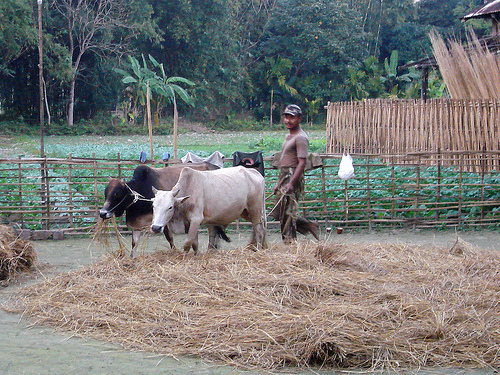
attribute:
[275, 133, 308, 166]
shirt — tan, brown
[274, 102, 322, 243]
man — walking, bare foot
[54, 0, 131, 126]
tree — green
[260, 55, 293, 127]
tree — green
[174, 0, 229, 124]
tree — green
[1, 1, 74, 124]
tree — green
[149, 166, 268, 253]
cow — walking, eating, cream, white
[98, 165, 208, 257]
cow — walking, eating, black, brown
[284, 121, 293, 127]
mustache — dark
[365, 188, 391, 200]
plant — green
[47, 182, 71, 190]
plant — green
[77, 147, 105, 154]
plant — green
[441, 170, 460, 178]
plant — green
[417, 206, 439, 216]
plant — green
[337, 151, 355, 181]
bag — white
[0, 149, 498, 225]
fence — tall, wooden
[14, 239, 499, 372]
pile of hay — brown, dry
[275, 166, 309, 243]
pants — dark